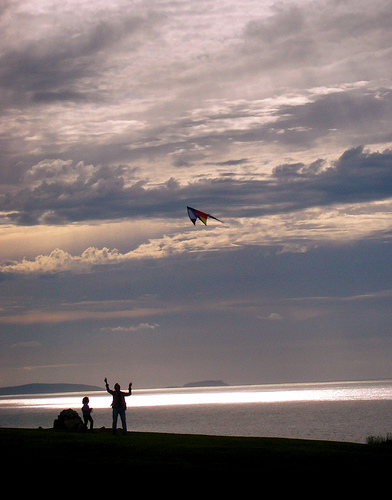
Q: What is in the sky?
A: Kite.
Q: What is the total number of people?
A: 2.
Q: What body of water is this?
A: Ocean.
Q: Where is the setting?
A: In nature.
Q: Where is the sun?
A: Covered by clouds.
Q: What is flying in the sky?
A: Kite.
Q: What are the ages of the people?
A: Child and adult.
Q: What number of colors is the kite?
A: 3.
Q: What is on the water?
A: Glare.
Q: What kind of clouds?
A: Storm clouds.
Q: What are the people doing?
A: Flying a kite.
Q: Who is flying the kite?
A: The adult.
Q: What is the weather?
A: Partly cloudy.